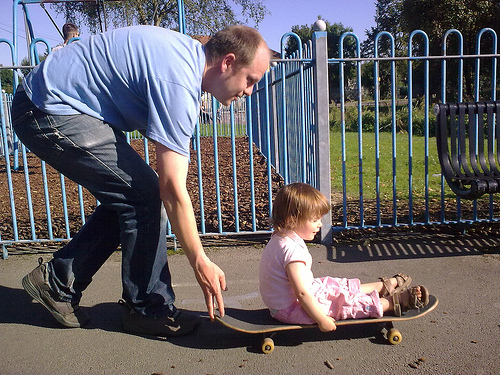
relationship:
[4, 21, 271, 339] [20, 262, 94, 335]
man has brown boot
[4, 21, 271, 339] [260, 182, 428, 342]
man pushing child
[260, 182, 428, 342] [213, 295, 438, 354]
child on skateboard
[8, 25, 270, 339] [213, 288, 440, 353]
father leaning over to touch skateboard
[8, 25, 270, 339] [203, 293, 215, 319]
father with finger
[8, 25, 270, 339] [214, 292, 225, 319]
father with finger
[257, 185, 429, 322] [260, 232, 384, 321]
girl wearing pink outfit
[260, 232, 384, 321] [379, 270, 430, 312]
pink outfit with brown sandals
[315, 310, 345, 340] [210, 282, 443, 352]
hand holding onto edge of skateboard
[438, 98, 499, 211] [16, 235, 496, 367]
bench on sidewalk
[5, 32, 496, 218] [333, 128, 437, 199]
fencing separating area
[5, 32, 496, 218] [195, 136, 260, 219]
fencing separating area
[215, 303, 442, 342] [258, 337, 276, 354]
skateboard has wheel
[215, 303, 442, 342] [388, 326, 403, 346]
skateboard has wheel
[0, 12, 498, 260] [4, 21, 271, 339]
railing behind man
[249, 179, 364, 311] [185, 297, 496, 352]
kid sitting on skateboard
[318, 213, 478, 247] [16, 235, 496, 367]
shadow on sidewalk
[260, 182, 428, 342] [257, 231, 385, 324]
child wearing outfit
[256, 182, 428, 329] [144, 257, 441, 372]
daughter seated on skateboard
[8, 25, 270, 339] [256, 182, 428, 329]
father pushing daughter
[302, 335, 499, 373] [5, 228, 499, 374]
wood chips on walkway